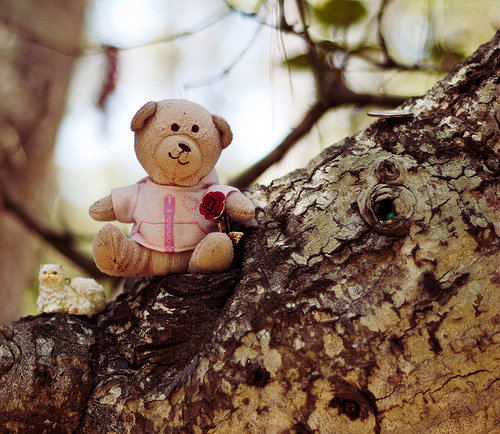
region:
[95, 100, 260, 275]
a teddy bear in a tree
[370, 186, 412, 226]
a knot in a tree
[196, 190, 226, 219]
a small red rose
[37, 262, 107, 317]
a small knit cat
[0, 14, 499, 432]
the trunk of a tree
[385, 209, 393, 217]
small green object in a tree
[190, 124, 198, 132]
eye of a teddy bear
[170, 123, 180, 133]
eye of a teddy bear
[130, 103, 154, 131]
ear of a teddy bear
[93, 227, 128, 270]
foot of a teddy bear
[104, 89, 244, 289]
small brown teddy bear sitting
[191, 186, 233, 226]
red rose with stem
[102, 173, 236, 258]
small pink shirt on teddy bear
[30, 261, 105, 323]
small white cat figurine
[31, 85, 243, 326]
teddy bear sitting next to cat figurine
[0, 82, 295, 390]
teddy bear and cat sitting on log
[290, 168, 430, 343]
different colored bark on log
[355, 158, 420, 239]
knot in tree log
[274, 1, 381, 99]
green leaves on branches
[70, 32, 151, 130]
brown leaf hanging down from branch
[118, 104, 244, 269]
brown teddy bear in tree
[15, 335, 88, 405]
brown and tan tree bark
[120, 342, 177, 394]
brown and tan tree bark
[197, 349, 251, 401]
brown and tan tree bark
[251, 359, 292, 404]
brown and tan tree bark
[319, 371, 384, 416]
brown and tan tree bark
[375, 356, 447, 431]
brown and tan tree bark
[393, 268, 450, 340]
brown and tan tree bark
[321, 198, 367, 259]
brown and tan tree bark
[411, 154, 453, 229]
brown and tan tree bark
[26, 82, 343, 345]
A childs things on a tree branch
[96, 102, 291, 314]
Teddy bear on a branch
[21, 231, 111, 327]
Cat ornament on a tree branch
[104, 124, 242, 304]
Teddy bear is wearing a pink hoodie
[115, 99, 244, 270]
Teddy bear is wearing a pink hoodie with a hood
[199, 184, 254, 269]
A gold pin with a red rose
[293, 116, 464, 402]
Branch of a tree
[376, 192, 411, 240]
Small green object in hole of tree branch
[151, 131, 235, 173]
Teddy bear has a crooked smile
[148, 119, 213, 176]
Crooked nose and mouth of teddy bear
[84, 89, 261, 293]
a bear on the branch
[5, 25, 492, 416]
the bark is brown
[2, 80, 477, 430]
the bark is cracked and splitting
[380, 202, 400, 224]
something green in the hole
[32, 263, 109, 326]
a toy cat on the branch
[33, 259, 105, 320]
the cat is white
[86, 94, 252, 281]
the bear is holding a rose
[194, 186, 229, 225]
the rose is red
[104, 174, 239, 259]
the shirt is pink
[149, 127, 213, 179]
the nose is crooked